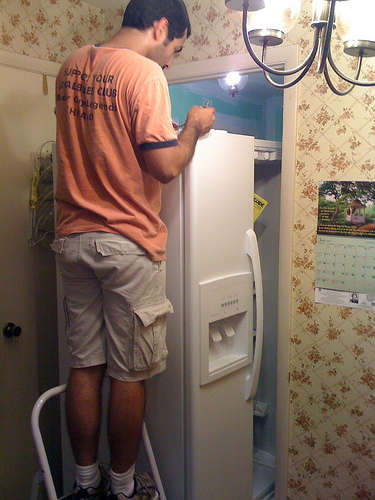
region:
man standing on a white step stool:
[15, 1, 209, 498]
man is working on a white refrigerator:
[33, 1, 300, 498]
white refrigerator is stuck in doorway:
[173, 121, 297, 498]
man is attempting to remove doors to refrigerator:
[40, 1, 230, 497]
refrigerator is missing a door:
[162, 124, 289, 496]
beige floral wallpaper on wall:
[293, 113, 370, 498]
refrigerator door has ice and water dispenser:
[182, 124, 257, 496]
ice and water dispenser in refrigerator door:
[180, 123, 250, 494]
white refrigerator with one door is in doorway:
[38, 120, 295, 495]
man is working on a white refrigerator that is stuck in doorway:
[54, 39, 307, 495]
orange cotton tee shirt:
[54, 43, 172, 263]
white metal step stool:
[24, 375, 168, 499]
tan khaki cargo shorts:
[52, 233, 170, 382]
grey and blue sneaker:
[110, 470, 156, 499]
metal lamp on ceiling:
[224, 2, 374, 93]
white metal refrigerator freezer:
[49, 126, 277, 498]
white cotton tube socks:
[74, 460, 135, 497]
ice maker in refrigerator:
[204, 308, 251, 373]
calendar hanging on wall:
[314, 179, 374, 312]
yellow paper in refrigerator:
[253, 192, 268, 222]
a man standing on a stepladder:
[53, 1, 215, 496]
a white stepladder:
[30, 383, 166, 497]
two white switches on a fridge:
[210, 318, 233, 343]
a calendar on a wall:
[316, 180, 374, 309]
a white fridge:
[57, 127, 264, 498]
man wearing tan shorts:
[50, 232, 174, 384]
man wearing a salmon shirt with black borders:
[54, 43, 177, 263]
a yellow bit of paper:
[254, 193, 266, 224]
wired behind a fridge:
[29, 138, 54, 256]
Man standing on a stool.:
[30, 0, 216, 495]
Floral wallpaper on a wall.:
[288, 6, 373, 498]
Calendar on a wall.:
[311, 177, 374, 313]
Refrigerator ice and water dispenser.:
[199, 267, 254, 384]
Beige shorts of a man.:
[51, 230, 170, 383]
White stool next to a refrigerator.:
[27, 374, 168, 497]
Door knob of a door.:
[2, 311, 23, 341]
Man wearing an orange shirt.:
[45, 2, 209, 262]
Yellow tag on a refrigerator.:
[252, 192, 267, 226]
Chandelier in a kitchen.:
[216, 0, 374, 96]